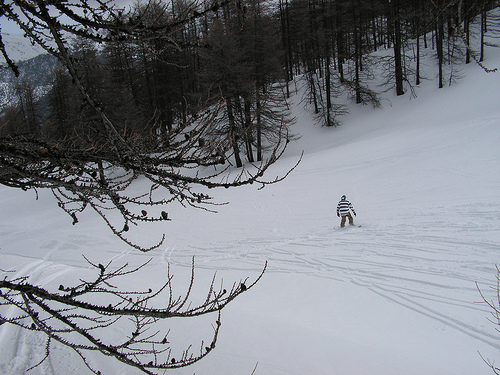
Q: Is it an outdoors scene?
A: Yes, it is outdoors.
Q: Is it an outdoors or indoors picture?
A: It is outdoors.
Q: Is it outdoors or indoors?
A: It is outdoors.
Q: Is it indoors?
A: No, it is outdoors.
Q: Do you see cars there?
A: No, there are no cars.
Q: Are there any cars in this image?
A: No, there are no cars.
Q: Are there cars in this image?
A: No, there are no cars.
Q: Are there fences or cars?
A: No, there are no cars or fences.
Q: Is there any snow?
A: Yes, there is snow.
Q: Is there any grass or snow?
A: Yes, there is snow.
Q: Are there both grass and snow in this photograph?
A: No, there is snow but no grass.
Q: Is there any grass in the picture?
A: No, there is no grass.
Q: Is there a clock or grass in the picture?
A: No, there are no grass or clocks.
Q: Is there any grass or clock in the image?
A: No, there are no grass or clocks.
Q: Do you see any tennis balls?
A: No, there are no tennis balls.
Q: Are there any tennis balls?
A: No, there are no tennis balls.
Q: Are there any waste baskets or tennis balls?
A: No, there are no tennis balls or waste baskets.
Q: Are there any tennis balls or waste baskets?
A: No, there are no tennis balls or waste baskets.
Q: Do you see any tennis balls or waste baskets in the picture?
A: No, there are no tennis balls or waste baskets.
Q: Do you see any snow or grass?
A: Yes, there is snow.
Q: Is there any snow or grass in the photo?
A: Yes, there is snow.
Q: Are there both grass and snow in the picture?
A: No, there is snow but no grass.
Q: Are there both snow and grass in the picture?
A: No, there is snow but no grass.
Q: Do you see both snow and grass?
A: No, there is snow but no grass.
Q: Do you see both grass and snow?
A: No, there is snow but no grass.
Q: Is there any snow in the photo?
A: Yes, there is snow.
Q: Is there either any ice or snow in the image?
A: Yes, there is snow.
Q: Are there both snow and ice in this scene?
A: No, there is snow but no ice.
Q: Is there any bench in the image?
A: No, there are no benches.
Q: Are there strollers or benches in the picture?
A: No, there are no benches or strollers.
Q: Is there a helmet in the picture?
A: No, there are no helmets.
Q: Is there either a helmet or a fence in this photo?
A: No, there are no helmets or fences.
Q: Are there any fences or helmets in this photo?
A: No, there are no helmets or fences.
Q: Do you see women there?
A: No, there are no women.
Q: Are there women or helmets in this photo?
A: No, there are no women or helmets.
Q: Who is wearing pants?
A: The man is wearing pants.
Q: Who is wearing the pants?
A: The man is wearing pants.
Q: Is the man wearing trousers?
A: Yes, the man is wearing trousers.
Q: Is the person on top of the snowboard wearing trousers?
A: Yes, the man is wearing trousers.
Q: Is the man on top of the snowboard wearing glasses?
A: No, the man is wearing trousers.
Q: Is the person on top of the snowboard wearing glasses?
A: No, the man is wearing trousers.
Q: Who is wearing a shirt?
A: The man is wearing a shirt.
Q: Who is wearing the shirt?
A: The man is wearing a shirt.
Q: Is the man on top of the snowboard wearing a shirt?
A: Yes, the man is wearing a shirt.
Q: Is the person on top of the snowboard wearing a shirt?
A: Yes, the man is wearing a shirt.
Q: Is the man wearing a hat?
A: No, the man is wearing a shirt.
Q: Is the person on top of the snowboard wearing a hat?
A: No, the man is wearing a shirt.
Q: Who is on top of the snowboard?
A: The man is on top of the snowboard.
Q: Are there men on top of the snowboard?
A: Yes, there is a man on top of the snowboard.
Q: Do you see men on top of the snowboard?
A: Yes, there is a man on top of the snowboard.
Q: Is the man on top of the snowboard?
A: Yes, the man is on top of the snowboard.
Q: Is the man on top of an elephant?
A: No, the man is on top of the snowboard.